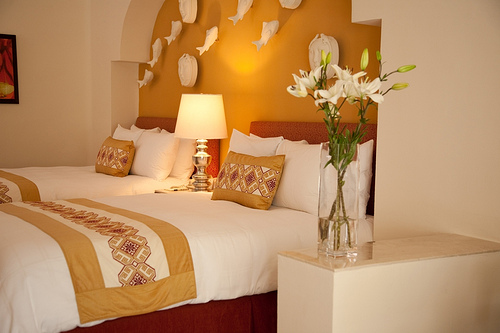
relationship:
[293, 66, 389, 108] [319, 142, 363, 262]
lillies in vase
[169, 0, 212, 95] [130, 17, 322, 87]
masks hanging on wall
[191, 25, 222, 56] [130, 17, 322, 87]
fish on wall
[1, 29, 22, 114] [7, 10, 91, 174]
painting on wall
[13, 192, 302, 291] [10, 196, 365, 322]
comforter on top of bed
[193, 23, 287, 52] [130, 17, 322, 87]
art hanging on wall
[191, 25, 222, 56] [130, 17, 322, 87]
fish hanging on wall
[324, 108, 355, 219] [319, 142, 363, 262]
stems inside vase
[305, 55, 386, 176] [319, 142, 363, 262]
flowers in vase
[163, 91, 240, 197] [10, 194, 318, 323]
lamp between bed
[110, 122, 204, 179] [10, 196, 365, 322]
pillows on bed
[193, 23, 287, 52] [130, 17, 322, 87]
art on wall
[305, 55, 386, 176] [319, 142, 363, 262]
flowers inside vase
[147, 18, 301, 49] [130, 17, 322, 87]
fishes on wall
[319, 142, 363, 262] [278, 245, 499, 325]
vase on top of table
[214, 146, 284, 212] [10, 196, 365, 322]
pillow on top of bed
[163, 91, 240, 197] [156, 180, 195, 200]
lamp on top of table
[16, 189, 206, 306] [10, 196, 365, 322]
blanket on bed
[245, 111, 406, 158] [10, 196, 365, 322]
headboard on back of bed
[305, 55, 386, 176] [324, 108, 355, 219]
flowers has stems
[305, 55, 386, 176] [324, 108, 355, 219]
flowers on stems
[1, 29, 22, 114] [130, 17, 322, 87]
picture on side of wall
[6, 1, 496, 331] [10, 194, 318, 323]
room has bed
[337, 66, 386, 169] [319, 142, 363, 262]
lillies in vase